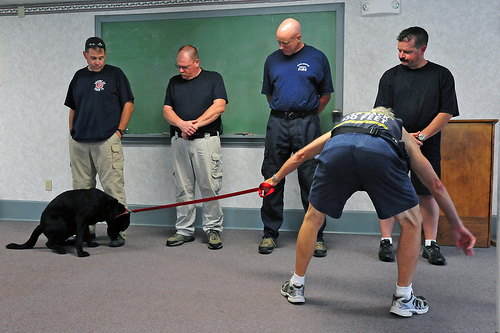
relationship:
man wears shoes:
[261, 107, 478, 315] [271, 271, 438, 318]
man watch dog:
[64, 36, 134, 241] [7, 180, 138, 264]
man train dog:
[261, 107, 478, 315] [7, 188, 127, 261]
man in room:
[368, 25, 458, 265] [1, 2, 498, 323]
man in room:
[252, 16, 335, 258] [1, 2, 498, 323]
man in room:
[160, 45, 223, 250] [1, 2, 498, 323]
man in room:
[64, 36, 134, 241] [1, 2, 498, 323]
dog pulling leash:
[4, 188, 131, 257] [198, 192, 210, 206]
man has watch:
[64, 36, 134, 241] [112, 124, 131, 139]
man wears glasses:
[261, 107, 478, 315] [176, 60, 191, 71]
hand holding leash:
[258, 179, 280, 204] [123, 180, 280, 215]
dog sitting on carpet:
[7, 188, 127, 261] [2, 220, 497, 330]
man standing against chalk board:
[160, 45, 229, 250] [93, 2, 345, 144]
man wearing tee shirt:
[256, 16, 334, 258] [259, 44, 334, 111]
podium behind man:
[423, 118, 499, 249] [368, 25, 458, 265]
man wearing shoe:
[261, 107, 478, 317] [267, 279, 313, 310]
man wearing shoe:
[261, 107, 478, 317] [387, 294, 430, 323]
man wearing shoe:
[160, 45, 229, 250] [166, 232, 193, 245]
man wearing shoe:
[160, 45, 229, 250] [200, 229, 224, 255]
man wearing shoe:
[256, 16, 334, 258] [308, 239, 329, 259]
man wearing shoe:
[368, 25, 458, 265] [419, 238, 447, 265]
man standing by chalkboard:
[70, 36, 138, 242] [90, 0, 347, 153]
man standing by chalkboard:
[160, 45, 229, 250] [90, 0, 347, 153]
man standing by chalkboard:
[256, 16, 334, 258] [90, 0, 347, 153]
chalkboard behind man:
[90, 0, 347, 153] [64, 36, 134, 241]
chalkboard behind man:
[90, 0, 347, 153] [160, 45, 229, 250]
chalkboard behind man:
[90, 0, 347, 153] [252, 16, 335, 258]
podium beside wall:
[428, 114, 497, 254] [2, 0, 498, 242]